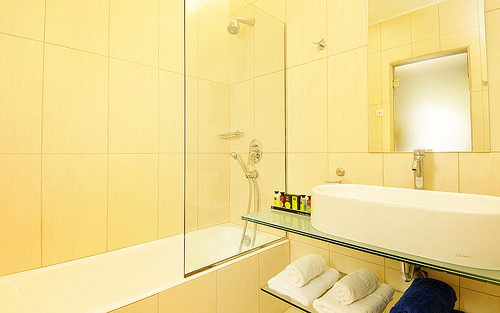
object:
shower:
[215, 15, 268, 255]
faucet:
[228, 134, 262, 181]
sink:
[308, 183, 499, 264]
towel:
[282, 245, 332, 287]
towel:
[390, 275, 460, 313]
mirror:
[369, 58, 479, 157]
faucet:
[407, 147, 425, 187]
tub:
[0, 220, 285, 311]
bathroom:
[0, 0, 500, 311]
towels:
[266, 258, 310, 297]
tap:
[406, 141, 429, 189]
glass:
[182, 0, 291, 277]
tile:
[0, 0, 500, 313]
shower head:
[224, 14, 255, 37]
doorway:
[390, 47, 469, 155]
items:
[268, 188, 316, 217]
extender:
[220, 182, 261, 253]